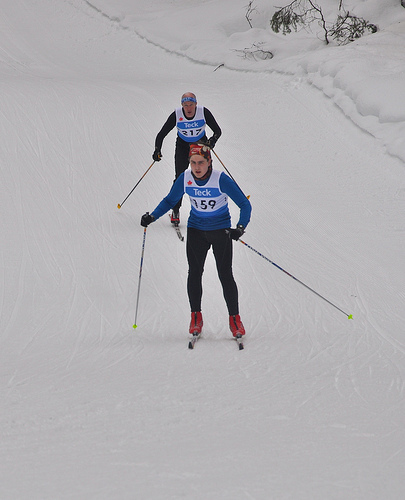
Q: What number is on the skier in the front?
A: 159.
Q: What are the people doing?
A: Skiing.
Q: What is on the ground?
A: Snow.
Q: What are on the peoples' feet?
A: Skis.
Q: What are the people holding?
A: Ski poles.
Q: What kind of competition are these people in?
A: Skiing.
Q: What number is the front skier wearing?
A: 159.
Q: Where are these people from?
A: Canada.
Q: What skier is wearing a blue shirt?
A: Nearest.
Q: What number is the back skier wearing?
A: 317.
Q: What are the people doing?
A: Skiing.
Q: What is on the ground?
A: Snow.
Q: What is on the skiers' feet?
A: Skis.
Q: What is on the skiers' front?
A: Numbers.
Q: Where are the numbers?
A: On the skiers.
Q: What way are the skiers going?
A: Downhill.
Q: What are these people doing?
A: Skiing.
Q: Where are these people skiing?
A: On a mountain.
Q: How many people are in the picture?
A: Two.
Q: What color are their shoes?
A: Red.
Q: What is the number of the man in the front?
A: 159.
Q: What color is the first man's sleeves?
A: Blue.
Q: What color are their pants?
A: Black.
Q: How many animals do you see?
A: None.